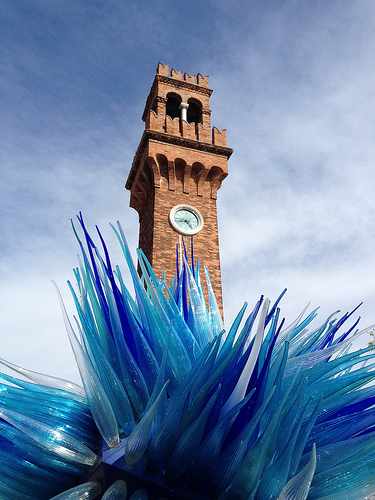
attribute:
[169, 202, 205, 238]
clock — big 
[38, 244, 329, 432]
blue flower — large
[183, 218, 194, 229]
hand — big 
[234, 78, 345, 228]
clouds — white 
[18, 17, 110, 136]
sky — blue 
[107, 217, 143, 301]
petal — clear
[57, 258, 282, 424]
flower — large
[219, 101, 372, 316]
clouds — white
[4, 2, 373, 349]
sky — blue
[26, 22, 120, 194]
sky — blue 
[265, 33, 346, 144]
sky — cloudy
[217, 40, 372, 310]
clouds — white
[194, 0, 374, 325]
sky — blue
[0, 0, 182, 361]
sky — blue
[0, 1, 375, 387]
clouds — white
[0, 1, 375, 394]
sky — blue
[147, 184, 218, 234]
clock — round 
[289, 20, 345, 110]
clouds — white 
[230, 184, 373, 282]
clouds — white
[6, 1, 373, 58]
sky — blue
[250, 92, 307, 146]
clouds — white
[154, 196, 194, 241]
clock — brick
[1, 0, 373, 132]
sky — blue 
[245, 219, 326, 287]
clouds — white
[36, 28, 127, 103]
sky — blue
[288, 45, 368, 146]
sky — blue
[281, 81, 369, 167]
clouds — white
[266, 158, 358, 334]
clouds — white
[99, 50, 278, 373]
tower — large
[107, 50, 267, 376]
tower — brick